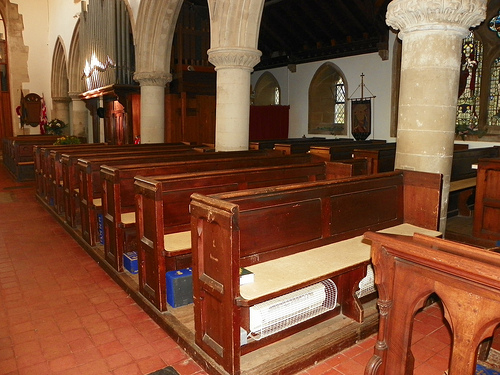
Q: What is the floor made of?
A: Bricks.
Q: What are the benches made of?
A: Wood.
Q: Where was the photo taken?
A: Church.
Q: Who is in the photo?
A: No one.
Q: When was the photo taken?
A: Daytime.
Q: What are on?
A: Lights.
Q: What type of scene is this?
A: Indoor.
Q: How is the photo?
A: Clear.